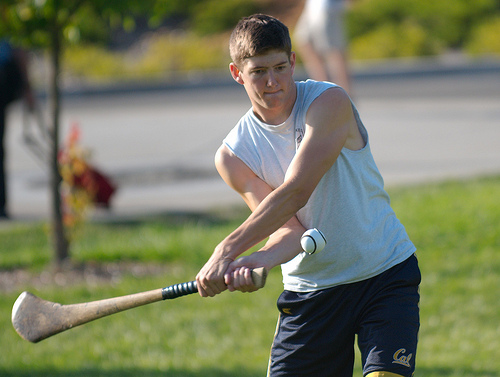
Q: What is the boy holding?
A: Wooden bat.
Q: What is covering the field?
A: Green grass.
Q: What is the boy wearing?
A: White tank top.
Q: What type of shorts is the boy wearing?
A: Blue shorts.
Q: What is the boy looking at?
A: Baseball.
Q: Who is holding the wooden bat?
A: The boy.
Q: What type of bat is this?
A: Brown wooden bat.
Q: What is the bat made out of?
A: Wood.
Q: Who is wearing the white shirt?
A: Boy.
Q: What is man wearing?
A: Blue shorts.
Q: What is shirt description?
A: Grey sleeveless.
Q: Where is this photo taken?
A: On a field.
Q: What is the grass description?
A: Green and lush.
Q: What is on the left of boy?
A: A small tree.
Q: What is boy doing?
A: Hitting ball.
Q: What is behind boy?
A: Asphalt area.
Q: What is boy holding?
A: A bat.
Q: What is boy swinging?
A: A bat.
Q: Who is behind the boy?
A: Another person.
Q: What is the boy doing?
A: Swinging a bat.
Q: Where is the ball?
A: In the air.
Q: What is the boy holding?
A: A bat.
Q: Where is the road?
A: Behind the boy.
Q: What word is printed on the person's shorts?
A: Cal.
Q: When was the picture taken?
A: Daytime.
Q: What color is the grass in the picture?
A: Green.